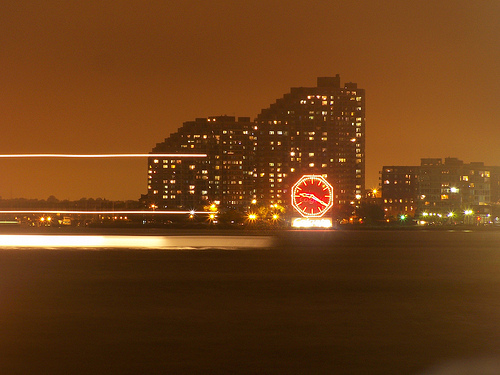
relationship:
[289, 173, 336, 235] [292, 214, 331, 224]
clock with lights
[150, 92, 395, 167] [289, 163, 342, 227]
buildings behind clock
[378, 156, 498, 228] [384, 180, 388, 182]
building with light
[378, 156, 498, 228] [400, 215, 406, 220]
building with glaring light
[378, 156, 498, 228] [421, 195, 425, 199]
building with light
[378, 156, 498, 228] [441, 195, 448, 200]
building with light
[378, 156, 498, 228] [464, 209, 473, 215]
building with glaring light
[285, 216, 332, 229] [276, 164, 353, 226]
light below clock